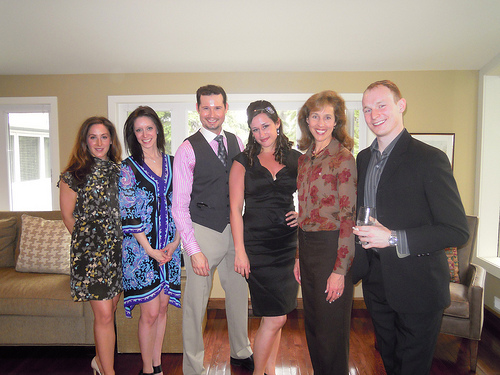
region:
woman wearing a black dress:
[227, 96, 303, 373]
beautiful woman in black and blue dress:
[115, 103, 184, 373]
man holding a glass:
[355, 77, 469, 374]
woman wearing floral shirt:
[288, 88, 360, 373]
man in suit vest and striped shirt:
[167, 83, 254, 373]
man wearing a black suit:
[350, 77, 467, 374]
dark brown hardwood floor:
[117, 306, 499, 373]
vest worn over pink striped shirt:
[169, 127, 245, 258]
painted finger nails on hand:
[322, 272, 346, 305]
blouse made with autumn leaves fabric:
[293, 135, 358, 277]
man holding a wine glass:
[348, 77, 471, 374]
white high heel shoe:
[88, 354, 104, 374]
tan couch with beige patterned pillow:
[1, 207, 186, 354]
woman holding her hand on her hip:
[226, 97, 305, 373]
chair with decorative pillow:
[438, 213, 488, 373]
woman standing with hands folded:
[116, 103, 184, 373]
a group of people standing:
[55, 90, 463, 282]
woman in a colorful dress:
[57, 114, 126, 329]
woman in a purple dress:
[122, 103, 185, 351]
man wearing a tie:
[180, 80, 233, 362]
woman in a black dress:
[237, 95, 297, 348]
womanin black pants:
[297, 83, 359, 363]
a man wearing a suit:
[352, 77, 446, 352]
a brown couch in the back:
[2, 193, 222, 370]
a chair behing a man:
[397, 197, 485, 356]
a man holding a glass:
[355, 80, 443, 320]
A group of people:
[49, 76, 473, 348]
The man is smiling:
[358, 70, 425, 157]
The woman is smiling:
[291, 89, 349, 159]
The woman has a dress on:
[231, 81, 297, 293]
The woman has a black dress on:
[231, 93, 290, 253]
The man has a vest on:
[181, 127, 226, 198]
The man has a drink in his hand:
[346, 70, 445, 252]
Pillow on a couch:
[19, 213, 66, 298]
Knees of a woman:
[134, 299, 166, 326]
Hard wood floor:
[288, 348, 304, 373]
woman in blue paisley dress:
[120, 141, 187, 316]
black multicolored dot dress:
[67, 143, 122, 307]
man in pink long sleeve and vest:
[175, 81, 240, 373]